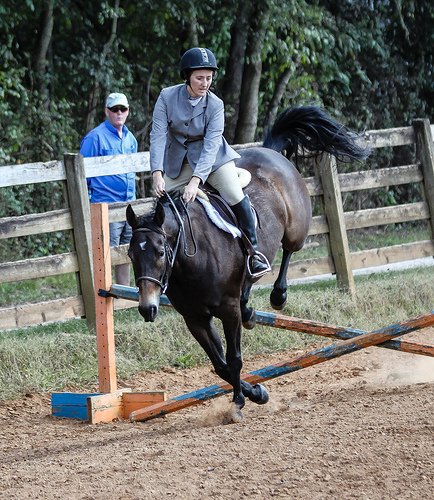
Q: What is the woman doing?
A: Riding a horse.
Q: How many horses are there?
A: One.